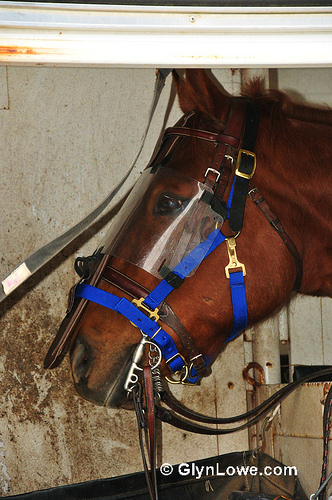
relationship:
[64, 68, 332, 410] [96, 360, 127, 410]
horse has mouth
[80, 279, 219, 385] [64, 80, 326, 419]
reigns on horse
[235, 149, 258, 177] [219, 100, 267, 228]
buckle on reign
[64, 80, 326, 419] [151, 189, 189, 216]
horse has eye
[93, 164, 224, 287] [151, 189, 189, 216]
plastic over eye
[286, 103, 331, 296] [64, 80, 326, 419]
neck on horse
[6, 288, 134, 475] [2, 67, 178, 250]
dirt on wall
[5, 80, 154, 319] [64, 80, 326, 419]
leash of horse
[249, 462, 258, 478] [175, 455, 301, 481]
letter "e" in word "glynlowe.com"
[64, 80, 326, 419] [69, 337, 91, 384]
horse has nose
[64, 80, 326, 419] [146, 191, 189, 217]
horse has eye